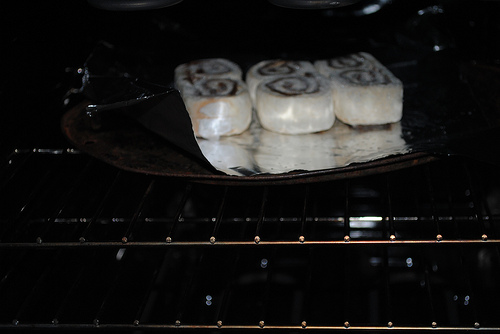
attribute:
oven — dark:
[1, 1, 499, 332]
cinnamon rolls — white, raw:
[170, 52, 408, 141]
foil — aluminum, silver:
[70, 61, 493, 177]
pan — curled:
[61, 51, 493, 185]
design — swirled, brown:
[198, 62, 233, 77]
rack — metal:
[10, 148, 499, 287]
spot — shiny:
[337, 199, 390, 235]